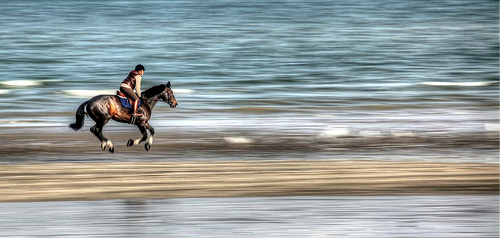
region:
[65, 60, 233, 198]
a horse is galloping across a sandbar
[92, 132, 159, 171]
the horse has all four hooves off the ground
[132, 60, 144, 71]
the rider has a black helmet on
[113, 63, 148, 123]
a girl is riding a horse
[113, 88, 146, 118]
the horse has a brown saddle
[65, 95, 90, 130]
the horse's tail is black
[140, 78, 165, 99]
the horse's mane is black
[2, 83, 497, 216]
the beach has a sandbar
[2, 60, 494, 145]
waves are hitting the beach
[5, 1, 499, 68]
the water is blue and rippled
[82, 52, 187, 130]
Person is riding a horse.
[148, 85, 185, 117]
The horse is brown.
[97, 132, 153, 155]
Part of the leg is white.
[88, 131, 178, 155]
The horse is in the air.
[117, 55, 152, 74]
The person is wearing a helmet.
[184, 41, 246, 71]
The water is blue.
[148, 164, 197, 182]
The stand is tan.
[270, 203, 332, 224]
The water is grey.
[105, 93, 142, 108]
There is a saddle on the horse.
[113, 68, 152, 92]
The vest is brown.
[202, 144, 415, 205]
Tan sandy area of beach.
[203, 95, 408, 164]
Blue water with white waves.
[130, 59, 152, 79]
Black hat on a woman.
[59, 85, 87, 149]
Black tail of a horse.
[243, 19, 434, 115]
Blue water with ripples.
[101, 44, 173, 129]
Girl riding on a horse.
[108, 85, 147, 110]
Brown riders pants.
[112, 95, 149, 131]
Brown horse riding boots.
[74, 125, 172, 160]
Black and white horse legs and hooves.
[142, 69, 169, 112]
A black horses mane.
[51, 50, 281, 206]
horse running along strip of beach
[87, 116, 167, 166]
horse's feet curled in air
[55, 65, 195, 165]
curve at the end of horse's tail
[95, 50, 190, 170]
rider leaning forward on horse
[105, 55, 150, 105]
rider wearing brown vest over tan shirt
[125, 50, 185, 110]
black mane over neck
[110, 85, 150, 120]
rider wearing knee-high boots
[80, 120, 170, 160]
black and white at end of horse's feet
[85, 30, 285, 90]
blue water with dark ripples in back of rider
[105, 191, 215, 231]
horse and rider's reflection in grey water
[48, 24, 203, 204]
Person riding on horse.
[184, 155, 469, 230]
Brown sand and blue water.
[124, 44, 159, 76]
Black riders hat.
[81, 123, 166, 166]
Black and white horse feet and legs.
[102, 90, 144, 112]
Brown and blue saddle.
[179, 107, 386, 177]
White capped waves.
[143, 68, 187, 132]
Black horses mane and ear.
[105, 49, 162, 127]
Woman on a horse.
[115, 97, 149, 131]
Brown horse rider boots.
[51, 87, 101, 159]
Black tail on horse.